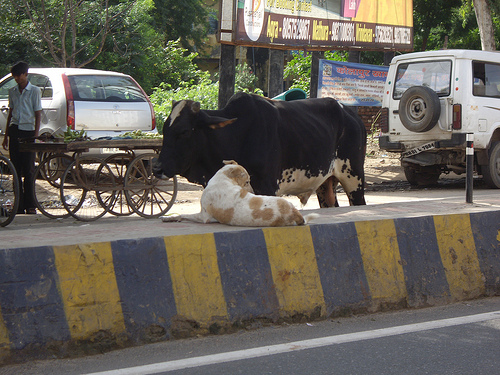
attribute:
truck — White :
[381, 44, 498, 199]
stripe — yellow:
[51, 238, 131, 351]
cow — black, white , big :
[132, 73, 378, 213]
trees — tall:
[3, 2, 220, 67]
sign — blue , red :
[318, 56, 389, 105]